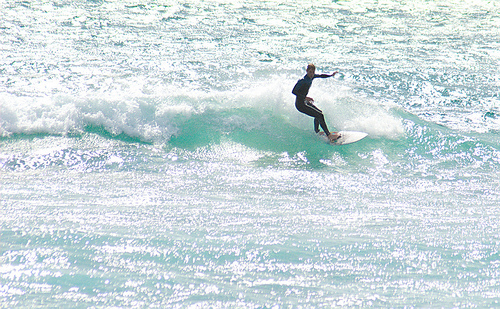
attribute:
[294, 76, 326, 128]
wet suit — black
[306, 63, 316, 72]
hair — short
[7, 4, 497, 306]
water — blue, body, white